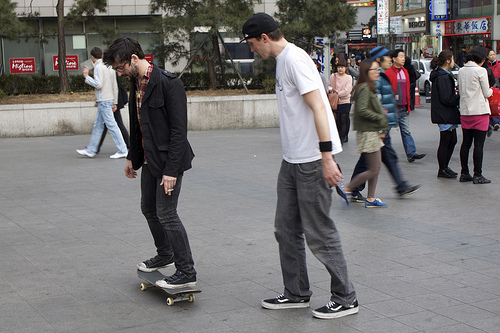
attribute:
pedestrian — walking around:
[333, 59, 389, 207]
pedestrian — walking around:
[340, 44, 420, 196]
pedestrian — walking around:
[382, 45, 425, 163]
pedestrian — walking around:
[427, 47, 462, 178]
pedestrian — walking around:
[454, 44, 496, 182]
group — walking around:
[332, 40, 495, 208]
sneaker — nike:
[313, 302, 361, 319]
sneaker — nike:
[259, 293, 312, 310]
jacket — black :
[113, 87, 195, 172]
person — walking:
[73, 44, 131, 161]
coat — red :
[385, 65, 412, 115]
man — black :
[242, 11, 370, 316]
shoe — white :
[315, 297, 357, 317]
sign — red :
[440, 15, 498, 39]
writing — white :
[453, 17, 490, 35]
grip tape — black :
[139, 268, 195, 295]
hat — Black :
[232, 14, 290, 49]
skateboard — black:
[126, 239, 184, 309]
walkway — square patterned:
[70, 87, 498, 319]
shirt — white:
[269, 45, 339, 160]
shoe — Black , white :
[155, 271, 196, 291]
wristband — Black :
[316, 138, 334, 153]